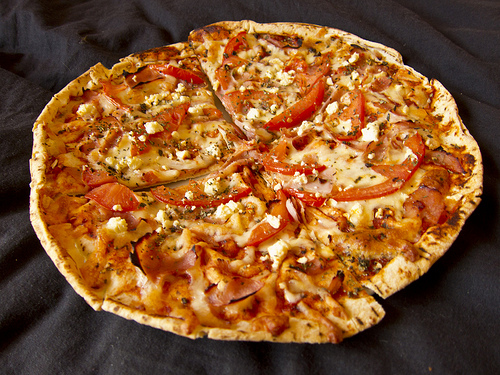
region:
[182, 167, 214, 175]
edge of a pizza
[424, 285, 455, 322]
part of a cloth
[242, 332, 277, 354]
edge of a pizza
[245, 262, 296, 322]
part of a pizza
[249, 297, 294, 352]
side of a pizza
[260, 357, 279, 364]
part of a sheet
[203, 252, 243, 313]
part of a pizza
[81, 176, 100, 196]
part of a tomato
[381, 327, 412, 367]
part of a duvet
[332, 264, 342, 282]
black mark is spotted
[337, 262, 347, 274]
black mark is spotted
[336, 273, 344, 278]
black mark is spotted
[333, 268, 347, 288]
black mark is spotted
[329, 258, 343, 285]
black mark is spotted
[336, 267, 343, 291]
black mark is spotted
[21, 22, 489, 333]
Round thin pizza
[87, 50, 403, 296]
Red sliced tomatoes on the pizza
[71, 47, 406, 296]
Cheese on the pizza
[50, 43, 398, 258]
The pizza has black and green seasoning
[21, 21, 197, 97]
The blanket is black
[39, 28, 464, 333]
The pizza is on top of the blanket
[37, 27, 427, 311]
The pizza is sliced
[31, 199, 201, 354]
The crust is thin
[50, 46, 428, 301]
There are four slices of pizza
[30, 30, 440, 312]
The pizza is brown, red, green, and yellow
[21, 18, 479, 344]
a whole pizza pie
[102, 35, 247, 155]
a slice of pizza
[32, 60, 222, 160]
a slice of pizza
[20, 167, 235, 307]
a slice of pizza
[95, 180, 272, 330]
a slice of pizza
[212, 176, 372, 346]
a slice of pizza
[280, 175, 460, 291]
a slice of pizza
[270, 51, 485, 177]
a slice of pizza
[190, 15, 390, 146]
a slice of pizza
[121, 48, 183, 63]
a burnt crust edge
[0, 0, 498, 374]
black background cloth framing homemade pizza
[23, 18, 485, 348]
pizza, i believe, is on a pita-type crust, maybe lavash, some other sort of flatbread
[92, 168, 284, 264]
again, prosciutto or some other sort of ham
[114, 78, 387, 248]
feta or goat cheese crumbles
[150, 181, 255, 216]
tomato, sliced very thinly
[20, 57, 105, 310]
curve/turned edge @ left side of crust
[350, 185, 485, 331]
sear marks more typical of lavash pizza than pizza crust pizza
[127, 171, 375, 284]
shaken spice, oregano maybe, atop pizza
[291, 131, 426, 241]
melted cheese beneath the shaken cheese, & amid the toppings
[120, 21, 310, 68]
a few singe marks at the edges of the crust, certain toppings. not a lot of burn, however. minimal